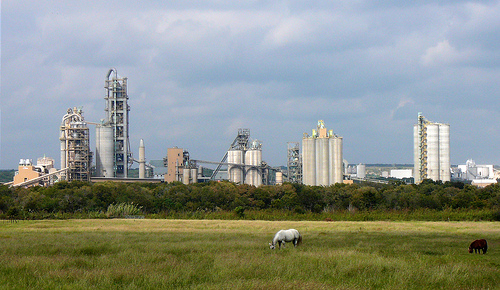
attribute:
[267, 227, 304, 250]
horse — white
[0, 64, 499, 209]
factory — large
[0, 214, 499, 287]
grass field — large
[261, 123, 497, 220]
building — large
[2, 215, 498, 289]
field — large, grassy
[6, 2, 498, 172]
cloudy sky — grey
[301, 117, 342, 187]
building — gray, industrial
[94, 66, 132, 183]
building — large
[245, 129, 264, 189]
silo — very large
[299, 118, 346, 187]
building — large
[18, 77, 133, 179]
tower — open-sided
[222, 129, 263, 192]
building — large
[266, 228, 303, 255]
horse — white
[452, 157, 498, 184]
building — large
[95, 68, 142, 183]
tower — gray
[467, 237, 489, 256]
horse — brown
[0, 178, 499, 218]
trees — large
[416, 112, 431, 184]
stairway — metal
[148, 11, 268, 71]
clouds — grey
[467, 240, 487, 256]
horse — black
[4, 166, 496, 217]
trees — small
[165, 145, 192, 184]
building — brown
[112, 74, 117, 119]
pipe — metal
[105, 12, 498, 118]
sky — covered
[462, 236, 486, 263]
horse — brown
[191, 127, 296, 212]
silo — very large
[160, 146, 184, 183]
structure — tan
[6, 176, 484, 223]
area — dense